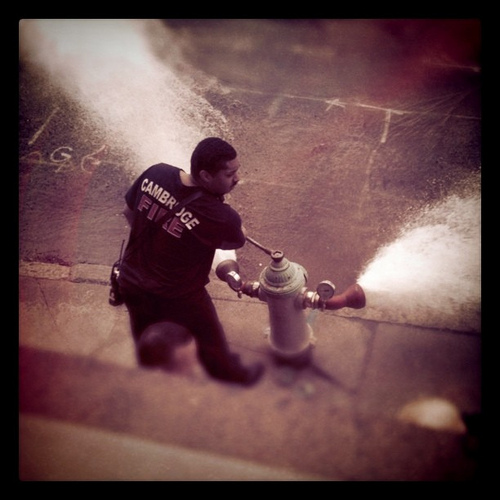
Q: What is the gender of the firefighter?
A: A male.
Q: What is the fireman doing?
A: Turning on the water from a fire hydrant.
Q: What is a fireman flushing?
A: A hydrant.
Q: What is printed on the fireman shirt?
A: CAMBRIDGE FIRE.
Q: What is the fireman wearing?
A: Black t-shirt and black pants.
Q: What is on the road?
A: Writing.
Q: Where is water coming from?
A: Hydrant.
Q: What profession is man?
A: Firefighter.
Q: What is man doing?
A: Opening hydrant.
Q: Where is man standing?
A: On sidewalk.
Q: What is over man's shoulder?
A: A strap.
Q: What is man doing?
A: Testing hydrant.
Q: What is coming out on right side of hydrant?
A: Gushing water.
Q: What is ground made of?
A: Concrete.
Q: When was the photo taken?
A: Daytime.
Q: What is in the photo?
A: A hydrant.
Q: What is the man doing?
A: Working.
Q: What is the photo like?
A: Black and white.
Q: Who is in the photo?
A: A man.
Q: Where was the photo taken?
A: From the second story.